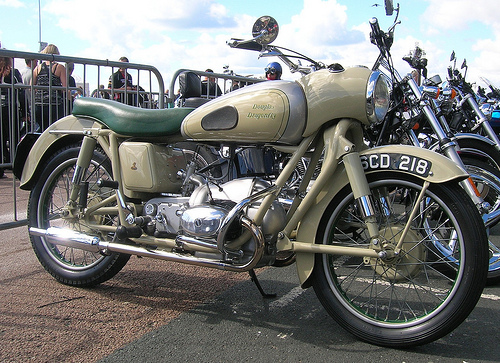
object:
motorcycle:
[173, 46, 500, 288]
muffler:
[28, 215, 265, 273]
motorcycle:
[11, 0, 490, 347]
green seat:
[71, 97, 197, 137]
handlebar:
[369, 17, 383, 38]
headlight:
[366, 70, 390, 125]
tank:
[180, 80, 307, 146]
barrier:
[0, 49, 165, 231]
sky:
[1, 2, 498, 95]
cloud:
[43, 1, 207, 42]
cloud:
[417, 1, 497, 34]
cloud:
[457, 35, 498, 92]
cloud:
[265, 1, 437, 88]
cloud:
[85, 30, 237, 82]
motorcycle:
[412, 48, 499, 145]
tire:
[310, 171, 489, 349]